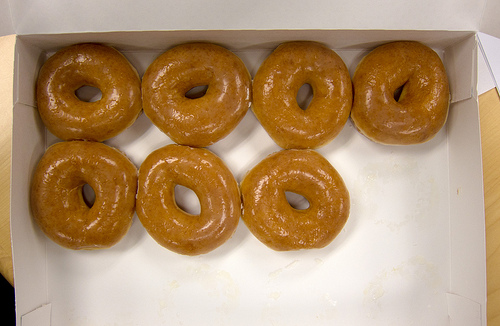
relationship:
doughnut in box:
[35, 41, 142, 140] [0, 0, 500, 325]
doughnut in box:
[145, 40, 249, 146] [0, 0, 500, 325]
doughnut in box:
[31, 143, 135, 249] [0, 0, 500, 325]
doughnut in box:
[135, 147, 241, 253] [0, 0, 500, 325]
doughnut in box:
[250, 40, 357, 152] [0, 0, 500, 325]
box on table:
[0, 0, 500, 325] [1, 35, 500, 324]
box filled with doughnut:
[0, 0, 500, 325] [145, 40, 249, 146]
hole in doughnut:
[75, 82, 106, 106] [35, 41, 142, 140]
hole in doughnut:
[181, 81, 212, 101] [145, 40, 249, 146]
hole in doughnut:
[291, 80, 317, 113] [250, 40, 357, 152]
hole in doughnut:
[75, 176, 100, 212] [31, 143, 135, 249]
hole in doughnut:
[172, 183, 206, 216] [135, 147, 241, 253]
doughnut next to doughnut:
[35, 41, 142, 140] [145, 40, 249, 146]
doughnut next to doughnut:
[145, 40, 249, 146] [250, 40, 357, 152]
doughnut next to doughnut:
[31, 143, 135, 249] [135, 147, 241, 253]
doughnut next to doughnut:
[35, 41, 142, 140] [31, 143, 135, 249]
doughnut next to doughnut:
[145, 40, 249, 146] [135, 147, 241, 253]